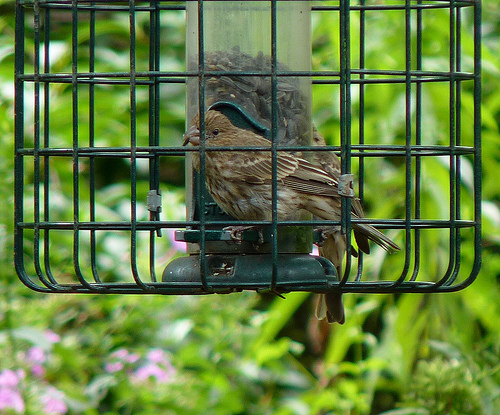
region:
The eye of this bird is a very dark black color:
[218, 101, 229, 166]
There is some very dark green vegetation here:
[237, 320, 287, 382]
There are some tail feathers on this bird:
[320, 185, 345, 242]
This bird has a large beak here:
[181, 131, 197, 153]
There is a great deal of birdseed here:
[231, 47, 271, 102]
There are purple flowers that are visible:
[7, 367, 24, 408]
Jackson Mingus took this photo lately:
[112, 40, 374, 411]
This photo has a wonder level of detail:
[78, 26, 404, 383]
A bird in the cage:
[216, 153, 267, 200]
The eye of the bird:
[212, 129, 218, 134]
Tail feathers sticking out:
[321, 297, 339, 314]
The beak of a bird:
[191, 129, 197, 140]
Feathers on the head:
[209, 111, 218, 119]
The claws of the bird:
[232, 227, 242, 231]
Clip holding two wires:
[342, 176, 349, 194]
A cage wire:
[14, 174, 20, 216]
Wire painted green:
[15, 180, 20, 219]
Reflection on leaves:
[146, 356, 170, 375]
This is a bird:
[159, 98, 386, 243]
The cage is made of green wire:
[6, 7, 498, 292]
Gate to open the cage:
[138, 5, 353, 271]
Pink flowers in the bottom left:
[3, 334, 185, 410]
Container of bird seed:
[182, 0, 322, 127]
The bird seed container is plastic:
[175, 3, 322, 130]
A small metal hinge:
[143, 183, 170, 217]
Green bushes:
[138, 308, 473, 410]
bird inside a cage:
[170, 92, 389, 269]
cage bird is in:
[12, 4, 480, 322]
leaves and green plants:
[2, 8, 487, 413]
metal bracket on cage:
[321, 169, 363, 201]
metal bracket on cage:
[139, 178, 169, 222]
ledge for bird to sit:
[175, 207, 330, 289]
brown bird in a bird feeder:
[176, 95, 406, 262]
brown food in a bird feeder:
[185, 2, 325, 127]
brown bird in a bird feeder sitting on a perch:
[169, 88, 399, 326]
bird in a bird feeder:
[171, 91, 396, 316]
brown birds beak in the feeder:
[176, 115, 196, 150]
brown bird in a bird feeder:
[175, 81, 405, 272]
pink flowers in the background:
[72, 340, 194, 381]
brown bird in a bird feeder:
[177, 120, 407, 262]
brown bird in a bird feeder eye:
[210, 125, 222, 132]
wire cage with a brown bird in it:
[6, 2, 121, 293]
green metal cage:
[13, 2, 480, 294]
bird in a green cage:
[181, 110, 400, 323]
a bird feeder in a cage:
[183, 0, 315, 258]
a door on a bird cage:
[151, 0, 349, 224]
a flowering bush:
[0, 311, 196, 413]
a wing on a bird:
[234, 136, 339, 195]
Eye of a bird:
[209, 123, 223, 140]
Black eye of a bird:
[210, 125, 222, 141]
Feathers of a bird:
[249, 164, 331, 206]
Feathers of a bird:
[275, 165, 321, 198]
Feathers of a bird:
[243, 155, 298, 208]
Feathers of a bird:
[257, 167, 342, 230]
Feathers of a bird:
[312, 187, 402, 254]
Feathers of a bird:
[223, 162, 299, 218]